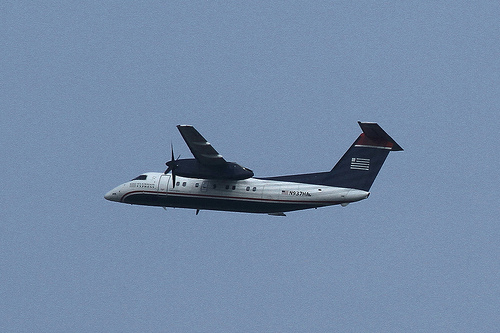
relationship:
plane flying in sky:
[103, 121, 403, 216] [1, 2, 500, 332]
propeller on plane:
[165, 144, 180, 190] [103, 121, 403, 216]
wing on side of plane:
[178, 125, 226, 164] [103, 121, 403, 216]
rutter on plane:
[358, 122, 403, 151] [103, 121, 403, 216]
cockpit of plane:
[103, 173, 148, 207] [103, 121, 403, 216]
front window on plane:
[134, 175, 148, 181] [103, 121, 403, 216]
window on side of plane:
[181, 180, 187, 189] [103, 121, 403, 216]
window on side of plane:
[176, 180, 180, 187] [103, 121, 403, 216]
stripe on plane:
[121, 190, 345, 204] [103, 121, 403, 216]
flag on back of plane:
[350, 157, 371, 172] [103, 121, 403, 216]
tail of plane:
[332, 122, 404, 189] [103, 121, 403, 216]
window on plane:
[224, 183, 230, 190] [103, 121, 403, 216]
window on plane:
[230, 185, 235, 191] [103, 121, 403, 216]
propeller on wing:
[165, 144, 180, 190] [178, 125, 226, 164]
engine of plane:
[173, 158, 255, 182] [103, 121, 403, 216]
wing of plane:
[178, 125, 226, 164] [103, 121, 403, 216]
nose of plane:
[104, 187, 117, 204] [103, 121, 403, 216]